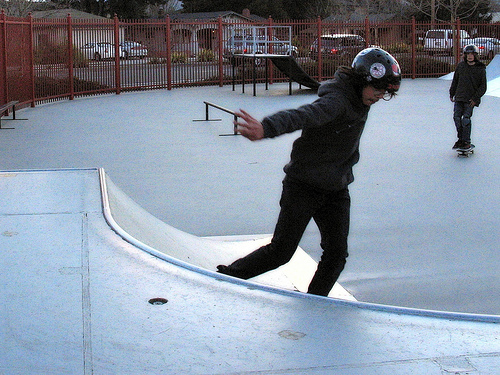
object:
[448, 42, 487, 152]
boy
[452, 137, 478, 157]
skateboard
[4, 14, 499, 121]
fence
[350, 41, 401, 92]
helmet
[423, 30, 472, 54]
van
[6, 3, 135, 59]
house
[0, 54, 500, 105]
street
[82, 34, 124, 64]
sedan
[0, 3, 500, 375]
skatepark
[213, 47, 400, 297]
boy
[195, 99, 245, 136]
grinding rail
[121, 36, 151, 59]
car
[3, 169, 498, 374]
ramp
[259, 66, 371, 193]
shirt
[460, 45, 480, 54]
helmet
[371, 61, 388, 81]
sticker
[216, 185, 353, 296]
jeans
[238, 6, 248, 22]
chimmney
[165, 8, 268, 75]
house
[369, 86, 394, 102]
reading glasses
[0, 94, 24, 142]
bench